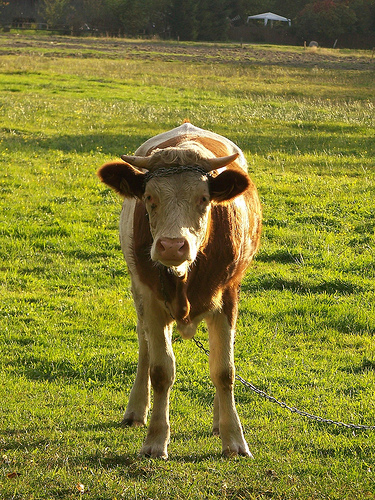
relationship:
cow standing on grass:
[92, 118, 268, 460] [1, 32, 363, 496]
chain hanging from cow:
[189, 332, 369, 442] [92, 118, 268, 460]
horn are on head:
[120, 155, 150, 170] [96, 144, 253, 277]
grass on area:
[1, 32, 363, 496] [2, 4, 374, 497]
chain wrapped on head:
[141, 163, 212, 187] [96, 144, 253, 277]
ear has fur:
[95, 159, 145, 199] [105, 168, 127, 187]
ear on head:
[96, 159, 145, 199] [96, 144, 253, 277]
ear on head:
[208, 167, 251, 203] [96, 144, 253, 277]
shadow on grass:
[10, 345, 138, 387] [9, 201, 366, 493]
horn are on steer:
[205, 151, 239, 173] [95, 142, 254, 276]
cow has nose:
[96, 119, 263, 459] [155, 232, 189, 261]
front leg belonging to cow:
[137, 292, 176, 459] [92, 118, 268, 460]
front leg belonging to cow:
[209, 282, 253, 455] [92, 118, 268, 460]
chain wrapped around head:
[141, 163, 211, 180] [96, 146, 253, 277]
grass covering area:
[1, 32, 363, 496] [2, 4, 374, 497]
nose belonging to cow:
[156, 237, 186, 261] [92, 118, 268, 460]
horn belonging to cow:
[120, 155, 150, 170] [92, 118, 268, 460]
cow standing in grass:
[92, 118, 268, 460] [1, 32, 363, 496]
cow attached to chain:
[92, 118, 268, 460] [141, 163, 362, 430]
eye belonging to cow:
[146, 194, 154, 200] [92, 118, 268, 460]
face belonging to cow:
[143, 167, 211, 268] [92, 118, 268, 460]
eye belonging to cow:
[199, 194, 209, 204] [92, 118, 268, 460]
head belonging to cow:
[96, 146, 253, 277] [92, 118, 268, 460]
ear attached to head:
[95, 159, 145, 199] [96, 146, 253, 277]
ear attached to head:
[208, 167, 251, 205] [96, 146, 253, 277]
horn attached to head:
[120, 152, 150, 171] [96, 146, 253, 277]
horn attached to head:
[205, 151, 239, 171] [96, 146, 253, 277]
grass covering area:
[1, 32, 363, 496] [2, 31, 363, 497]